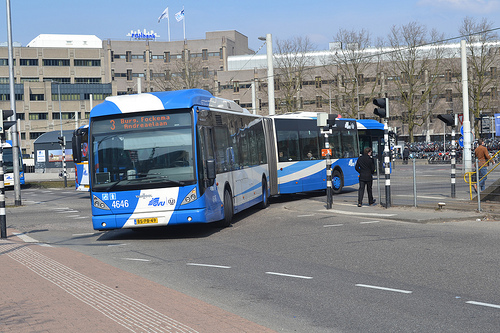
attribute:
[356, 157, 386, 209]
clothes — black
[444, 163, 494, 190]
railing — yellow